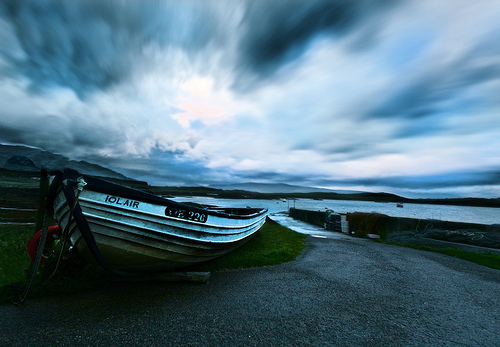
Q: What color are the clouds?
A: White.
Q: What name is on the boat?
A: Iolair.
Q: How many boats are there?
A: One.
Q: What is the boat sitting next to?
A: A road.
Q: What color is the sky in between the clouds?
A: Blue.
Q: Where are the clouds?
A: In the sky.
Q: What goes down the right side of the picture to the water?
A: A road.